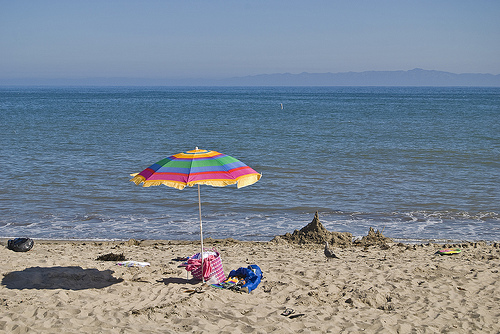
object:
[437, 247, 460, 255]
boogie board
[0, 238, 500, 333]
sand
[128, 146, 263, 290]
umbrella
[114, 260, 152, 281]
seagull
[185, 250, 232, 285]
beach bag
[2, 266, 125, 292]
shadow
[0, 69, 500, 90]
land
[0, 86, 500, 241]
water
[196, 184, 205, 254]
umbrella pole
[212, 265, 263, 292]
backpack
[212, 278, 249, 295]
towel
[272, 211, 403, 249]
sand castle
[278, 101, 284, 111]
buoy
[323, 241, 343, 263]
seagull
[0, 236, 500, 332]
beach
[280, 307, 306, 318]
flip flops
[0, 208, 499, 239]
waves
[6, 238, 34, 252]
object